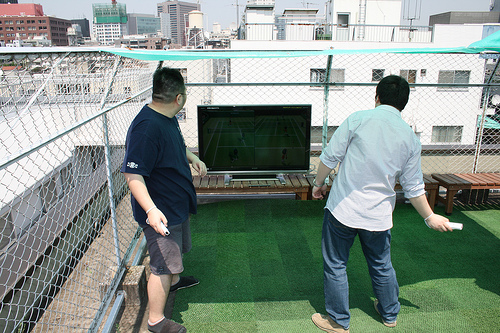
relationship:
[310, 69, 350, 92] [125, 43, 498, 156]
window on side of building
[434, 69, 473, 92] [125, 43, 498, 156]
window on building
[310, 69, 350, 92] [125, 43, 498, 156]
window on building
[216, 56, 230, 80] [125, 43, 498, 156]
window on side of building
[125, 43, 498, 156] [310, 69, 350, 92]
building has window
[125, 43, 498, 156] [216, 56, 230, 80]
building has window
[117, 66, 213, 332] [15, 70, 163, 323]
man next to fence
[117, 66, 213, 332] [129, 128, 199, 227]
man wearing t-shirt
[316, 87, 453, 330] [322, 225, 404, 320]
man wearing jeans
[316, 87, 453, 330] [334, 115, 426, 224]
man wearing shirt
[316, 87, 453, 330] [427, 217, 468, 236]
man holding control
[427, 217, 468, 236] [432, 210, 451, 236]
control in hand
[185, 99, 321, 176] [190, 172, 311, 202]
television on top of bench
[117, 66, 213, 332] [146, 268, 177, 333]
man has leg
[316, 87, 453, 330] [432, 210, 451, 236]
man has hand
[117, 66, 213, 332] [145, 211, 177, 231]
man has hand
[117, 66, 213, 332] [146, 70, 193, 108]
man has head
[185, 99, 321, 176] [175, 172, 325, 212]
television sitting on bench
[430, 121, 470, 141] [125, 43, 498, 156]
window on building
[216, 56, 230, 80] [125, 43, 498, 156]
window on building